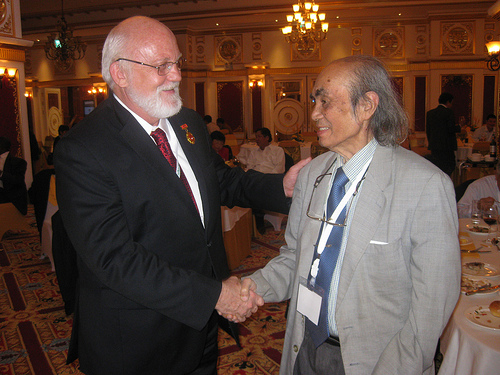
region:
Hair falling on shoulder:
[380, 117, 399, 142]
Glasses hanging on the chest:
[308, 217, 325, 222]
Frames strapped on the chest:
[315, 175, 319, 184]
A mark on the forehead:
[326, 78, 331, 81]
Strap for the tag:
[323, 234, 326, 241]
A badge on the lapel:
[185, 125, 192, 143]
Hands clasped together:
[225, 280, 256, 312]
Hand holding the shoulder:
[288, 161, 309, 196]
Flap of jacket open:
[65, 342, 72, 363]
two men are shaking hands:
[203, 243, 285, 345]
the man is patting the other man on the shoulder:
[276, 148, 329, 209]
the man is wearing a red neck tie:
[155, 128, 200, 238]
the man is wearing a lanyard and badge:
[293, 154, 375, 349]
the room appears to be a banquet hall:
[14, 36, 496, 373]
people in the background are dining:
[211, 113, 309, 163]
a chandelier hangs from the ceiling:
[274, 5, 335, 60]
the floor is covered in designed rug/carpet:
[5, 240, 67, 364]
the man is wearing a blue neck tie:
[298, 170, 343, 342]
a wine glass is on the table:
[478, 197, 498, 242]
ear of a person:
[356, 88, 380, 124]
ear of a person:
[105, 60, 135, 93]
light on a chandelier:
[320, 20, 330, 36]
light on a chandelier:
[302, 19, 314, 32]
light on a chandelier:
[281, 22, 292, 38]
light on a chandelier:
[285, 11, 295, 23]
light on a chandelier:
[291, 1, 299, 13]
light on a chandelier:
[310, 1, 322, 11]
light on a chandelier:
[484, 38, 497, 56]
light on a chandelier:
[307, 10, 317, 22]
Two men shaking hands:
[53, 13, 462, 373]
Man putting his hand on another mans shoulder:
[51, 13, 463, 373]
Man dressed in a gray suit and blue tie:
[233, 55, 462, 374]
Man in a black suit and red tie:
[50, 14, 312, 374]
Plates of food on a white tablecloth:
[429, 215, 498, 372]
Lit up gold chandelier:
[275, 0, 327, 57]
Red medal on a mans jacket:
[176, 119, 196, 146]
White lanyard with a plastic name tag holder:
[291, 146, 377, 328]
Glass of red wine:
[481, 202, 498, 237]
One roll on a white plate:
[465, 299, 499, 332]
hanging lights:
[275, 0, 335, 62]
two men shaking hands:
[47, 12, 466, 372]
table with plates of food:
[437, 203, 499, 374]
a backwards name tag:
[287, 271, 328, 328]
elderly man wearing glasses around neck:
[292, 54, 401, 232]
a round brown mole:
[323, 77, 331, 84]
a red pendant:
[180, 121, 197, 145]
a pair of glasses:
[107, 50, 187, 77]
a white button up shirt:
[242, 143, 287, 175]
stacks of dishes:
[465, 147, 493, 165]